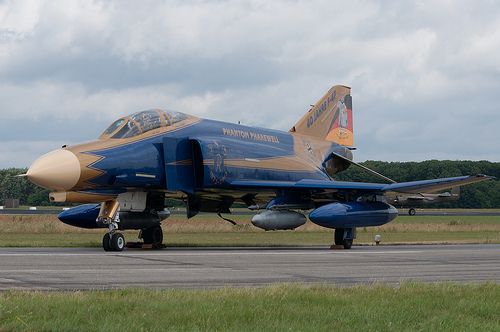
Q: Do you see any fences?
A: No, there are no fences.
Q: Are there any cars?
A: No, there are no cars.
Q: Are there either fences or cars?
A: No, there are no cars or fences.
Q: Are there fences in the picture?
A: No, there are no fences.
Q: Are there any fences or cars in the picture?
A: No, there are no fences or cars.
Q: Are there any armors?
A: No, there are no armors.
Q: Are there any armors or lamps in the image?
A: No, there are no armors or lamps.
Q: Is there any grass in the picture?
A: Yes, there is grass.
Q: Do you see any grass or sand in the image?
A: Yes, there is grass.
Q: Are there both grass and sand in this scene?
A: No, there is grass but no sand.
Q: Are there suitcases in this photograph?
A: No, there are no suitcases.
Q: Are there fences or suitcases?
A: No, there are no suitcases or fences.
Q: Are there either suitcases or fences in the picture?
A: No, there are no suitcases or fences.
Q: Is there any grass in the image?
A: Yes, there is grass.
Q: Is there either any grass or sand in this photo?
A: Yes, there is grass.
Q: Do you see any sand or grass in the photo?
A: Yes, there is grass.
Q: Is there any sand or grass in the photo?
A: Yes, there is grass.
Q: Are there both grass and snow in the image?
A: No, there is grass but no snow.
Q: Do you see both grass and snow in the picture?
A: No, there is grass but no snow.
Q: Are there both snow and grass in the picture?
A: No, there is grass but no snow.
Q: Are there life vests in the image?
A: No, there are no life vests.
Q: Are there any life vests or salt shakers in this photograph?
A: No, there are no life vests or salt shakers.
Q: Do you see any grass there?
A: Yes, there is grass.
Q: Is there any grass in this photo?
A: Yes, there is grass.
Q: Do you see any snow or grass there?
A: Yes, there is grass.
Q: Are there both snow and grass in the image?
A: No, there is grass but no snow.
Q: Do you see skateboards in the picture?
A: No, there are no skateboards.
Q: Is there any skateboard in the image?
A: No, there are no skateboards.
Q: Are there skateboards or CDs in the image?
A: No, there are no skateboards or cds.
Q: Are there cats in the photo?
A: No, there are no cats.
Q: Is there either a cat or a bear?
A: No, there are no cats or bears.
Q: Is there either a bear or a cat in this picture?
A: No, there are no cats or bears.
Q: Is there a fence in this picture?
A: No, there are no fences.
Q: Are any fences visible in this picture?
A: No, there are no fences.